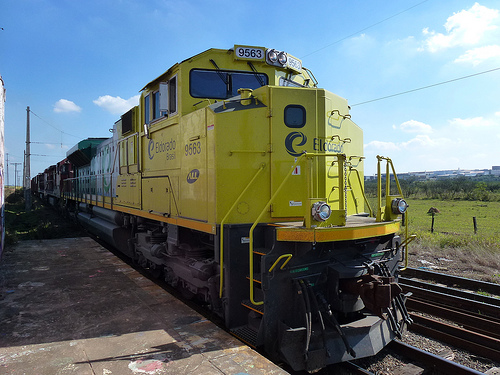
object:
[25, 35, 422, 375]
train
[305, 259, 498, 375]
tracks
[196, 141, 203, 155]
number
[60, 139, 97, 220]
train cars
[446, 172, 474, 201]
tree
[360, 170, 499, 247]
grass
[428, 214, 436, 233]
post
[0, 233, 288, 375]
platform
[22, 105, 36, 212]
tower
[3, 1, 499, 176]
sky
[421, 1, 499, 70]
clouds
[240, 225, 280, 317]
stairs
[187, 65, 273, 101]
window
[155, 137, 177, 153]
word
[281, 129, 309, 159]
logo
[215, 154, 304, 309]
rails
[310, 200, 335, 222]
headlight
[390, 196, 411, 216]
headlight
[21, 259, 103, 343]
paint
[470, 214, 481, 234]
post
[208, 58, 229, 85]
windshield wipers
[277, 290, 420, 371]
cattle guard